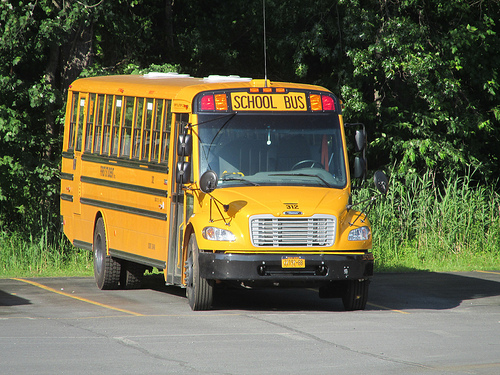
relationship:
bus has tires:
[58, 70, 374, 312] [92, 218, 372, 311]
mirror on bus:
[175, 160, 194, 184] [58, 70, 374, 312]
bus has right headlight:
[58, 70, 374, 312] [203, 225, 240, 243]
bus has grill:
[58, 70, 374, 312] [252, 214, 338, 246]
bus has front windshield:
[58, 70, 374, 312] [215, 172, 329, 184]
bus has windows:
[58, 70, 374, 312] [69, 91, 169, 167]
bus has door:
[58, 70, 374, 312] [168, 114, 191, 284]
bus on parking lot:
[58, 70, 374, 312] [4, 269, 499, 375]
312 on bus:
[285, 202, 299, 210] [58, 70, 374, 312]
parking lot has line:
[4, 269, 499, 375] [9, 271, 155, 320]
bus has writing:
[58, 70, 374, 312] [97, 163, 117, 180]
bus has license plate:
[58, 70, 374, 312] [279, 257, 309, 270]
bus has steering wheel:
[58, 70, 374, 312] [291, 156, 322, 172]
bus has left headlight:
[58, 70, 374, 312] [348, 225, 371, 243]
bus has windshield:
[58, 70, 374, 312] [215, 172, 329, 184]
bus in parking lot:
[58, 70, 374, 312] [4, 269, 499, 375]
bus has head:
[58, 70, 374, 312] [187, 83, 377, 294]